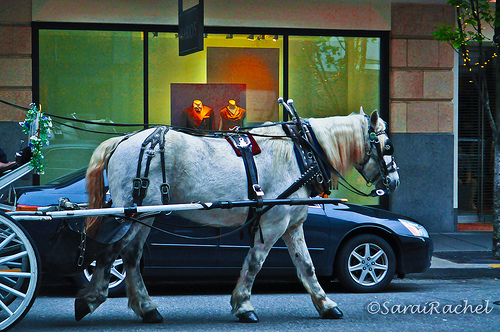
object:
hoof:
[233, 310, 258, 325]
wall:
[411, 136, 446, 159]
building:
[2, 1, 457, 221]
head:
[356, 107, 400, 197]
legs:
[229, 215, 289, 302]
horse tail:
[84, 136, 119, 239]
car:
[1, 150, 433, 292]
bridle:
[358, 114, 400, 196]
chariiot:
[0, 117, 40, 329]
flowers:
[20, 105, 53, 172]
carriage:
[0, 98, 53, 330]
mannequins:
[220, 100, 247, 131]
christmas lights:
[454, 2, 499, 74]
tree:
[426, 0, 498, 262]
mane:
[309, 116, 368, 186]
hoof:
[320, 307, 343, 318]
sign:
[177, 4, 202, 57]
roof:
[25, 0, 393, 32]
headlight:
[398, 218, 429, 238]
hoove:
[141, 307, 163, 322]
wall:
[44, 42, 354, 107]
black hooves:
[74, 302, 96, 322]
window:
[37, 22, 391, 219]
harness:
[273, 121, 332, 194]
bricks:
[391, 38, 408, 71]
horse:
[71, 106, 398, 324]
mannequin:
[182, 100, 215, 134]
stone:
[390, 101, 407, 131]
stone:
[407, 100, 439, 132]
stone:
[439, 101, 454, 131]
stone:
[391, 67, 424, 99]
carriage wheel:
[1, 210, 39, 327]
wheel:
[334, 234, 395, 290]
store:
[8, 4, 469, 249]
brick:
[422, 69, 454, 101]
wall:
[388, 6, 464, 135]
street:
[19, 273, 484, 328]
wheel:
[72, 239, 144, 297]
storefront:
[8, 19, 483, 218]